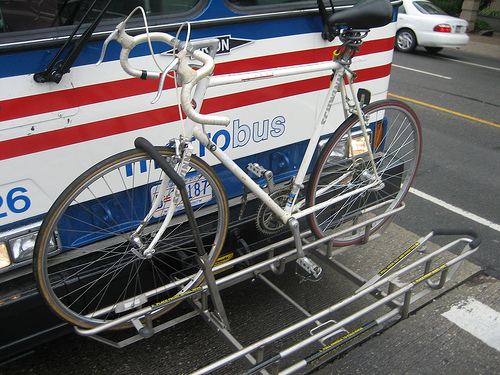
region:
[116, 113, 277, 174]
Metrobus with a bike on the front of it.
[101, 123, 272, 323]
Bike wheel that is attached to a metrobus.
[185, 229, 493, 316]
Bike rack on the metrobus.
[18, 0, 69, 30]
Window of the bus.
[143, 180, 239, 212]
Licence plate of the bus.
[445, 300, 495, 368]
White line on the road.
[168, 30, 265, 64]
Model of the bus.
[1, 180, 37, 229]
Number of the bus.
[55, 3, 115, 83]
Windshield wiper of the nus.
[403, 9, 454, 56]
White car across the street fron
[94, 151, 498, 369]
A METAL BIKE RACK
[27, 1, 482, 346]
A BIKE ON A BIKE RACK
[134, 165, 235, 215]
A LICENSE PLATE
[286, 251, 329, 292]
A BICYCLE PEDAL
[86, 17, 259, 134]
A PAIR OF WHITE HANDLE BARS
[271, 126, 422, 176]
HEADLIGHTS ON A BUS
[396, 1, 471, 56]
A CAR IN THE BACKGROUND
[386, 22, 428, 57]
REAR CAR TIRE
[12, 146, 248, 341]
FRONT BIKE WHEEL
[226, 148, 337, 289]
TWO BIKE PEDALS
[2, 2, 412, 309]
Passenger bus on the road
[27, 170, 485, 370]
Bus has a bike rack in front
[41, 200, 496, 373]
Rack feet two bikes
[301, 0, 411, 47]
Bike seat is black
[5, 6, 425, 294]
Bus is blue, red and white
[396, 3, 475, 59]
White car on the road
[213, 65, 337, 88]
Top tube of bike is white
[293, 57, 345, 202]
Seat tube is white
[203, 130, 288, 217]
Down tube is white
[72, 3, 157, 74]
Brake hoods is tan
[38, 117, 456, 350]
bicycle racks attached to front of a public bus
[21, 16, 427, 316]
white bicycle with harness over front wheel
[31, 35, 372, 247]
front of bus painted red white and blue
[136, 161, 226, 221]
license plate partially hidden by bicycle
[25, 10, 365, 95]
bottom of windshild wipers attached to bus frame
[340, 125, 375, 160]
lit headlight on bus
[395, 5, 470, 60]
rear of car parked at the curb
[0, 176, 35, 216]
last number of bus identification number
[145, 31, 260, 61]
bus manufacturer hidden by handlebar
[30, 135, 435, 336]
wheels covering black bumper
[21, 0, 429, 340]
a white bike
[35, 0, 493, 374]
the bike is in a bike rack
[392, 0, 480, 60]
the car is white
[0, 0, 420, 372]
the bus is red, white and blue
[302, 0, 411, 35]
the bike seat is black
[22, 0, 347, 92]
the windshield wipers are black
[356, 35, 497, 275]
a street is beside the bus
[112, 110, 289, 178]
the letters on the bus are blue and white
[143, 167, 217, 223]
a license plate is on the front of the bus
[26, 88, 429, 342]
the bicycle has two tires